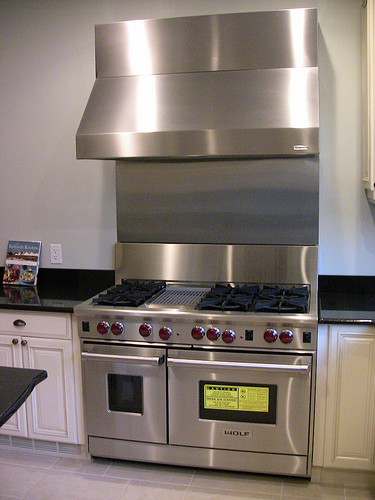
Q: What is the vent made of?
A: Metal.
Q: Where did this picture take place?
A: Kitchen.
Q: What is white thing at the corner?
A: Cabinets.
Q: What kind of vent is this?
A: Stainless steel.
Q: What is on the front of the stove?
A: Red knobs.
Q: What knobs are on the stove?
A: Red knobs.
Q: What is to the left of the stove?
A: White cabinets.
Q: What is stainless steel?
A: The oven and stove.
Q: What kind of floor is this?
A: A tile floor.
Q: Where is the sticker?
A: On oven door.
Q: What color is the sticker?
A: Yellow.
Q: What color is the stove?
A: Stainless steel.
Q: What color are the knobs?
A: Red.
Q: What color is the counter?
A: Black.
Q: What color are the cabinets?
A: White.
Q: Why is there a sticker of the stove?
A: It's new.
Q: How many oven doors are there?
A: Two.